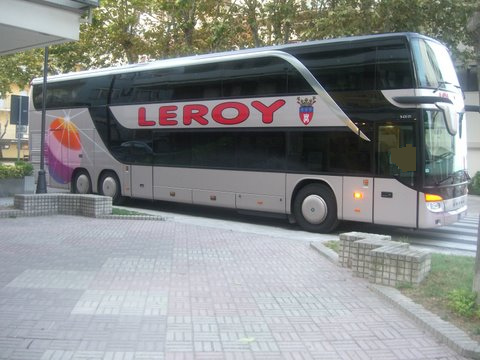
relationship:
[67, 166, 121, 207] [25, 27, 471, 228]
wheels on bus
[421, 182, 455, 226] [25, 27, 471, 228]
headlight on bus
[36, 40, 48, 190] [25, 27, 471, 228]
lamppost on bus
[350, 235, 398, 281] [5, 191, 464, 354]
bricks next to sidewalk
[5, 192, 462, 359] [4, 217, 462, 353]
bricks on sidewalk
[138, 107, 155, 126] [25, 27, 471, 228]
letter on bus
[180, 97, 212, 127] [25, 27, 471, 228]
letter on bus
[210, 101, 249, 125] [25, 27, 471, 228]
letter on bus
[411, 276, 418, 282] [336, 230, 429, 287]
brick on block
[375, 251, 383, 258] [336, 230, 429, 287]
brick on block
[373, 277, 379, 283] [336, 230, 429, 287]
brick on block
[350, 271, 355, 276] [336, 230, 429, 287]
brick on block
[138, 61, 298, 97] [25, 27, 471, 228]
tinted windows on bus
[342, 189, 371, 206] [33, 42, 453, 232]
yellow signal on bus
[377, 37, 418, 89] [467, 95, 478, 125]
window on building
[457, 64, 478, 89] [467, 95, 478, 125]
window on building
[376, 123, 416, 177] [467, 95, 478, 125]
window on building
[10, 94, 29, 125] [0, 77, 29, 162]
window on building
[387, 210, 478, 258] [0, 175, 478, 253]
crosswalk on street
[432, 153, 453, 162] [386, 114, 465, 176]
steering wheel in cockpit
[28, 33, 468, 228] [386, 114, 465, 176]
bus has cockpit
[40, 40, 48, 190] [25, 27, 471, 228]
lamppost near bus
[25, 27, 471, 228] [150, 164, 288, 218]
bus has luggage compartment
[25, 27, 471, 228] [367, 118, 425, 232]
bus has front door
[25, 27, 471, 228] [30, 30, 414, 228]
bus has side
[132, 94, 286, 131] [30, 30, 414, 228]
leroy on side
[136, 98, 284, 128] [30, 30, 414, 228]
leroy on side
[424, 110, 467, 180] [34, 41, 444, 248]
window on bus